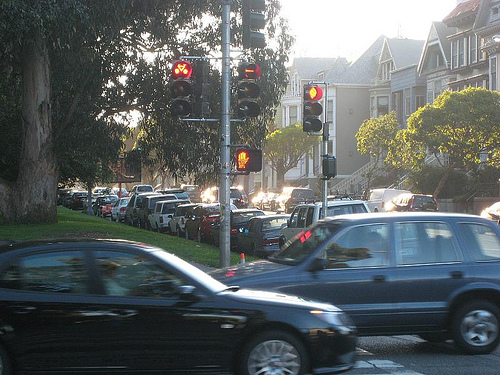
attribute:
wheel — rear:
[461, 306, 498, 350]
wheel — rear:
[251, 327, 293, 364]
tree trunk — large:
[14, 44, 68, 224]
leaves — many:
[92, 28, 159, 98]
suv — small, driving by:
[209, 210, 498, 352]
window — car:
[21, 246, 90, 301]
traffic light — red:
[302, 81, 323, 135]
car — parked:
[277, 200, 368, 255]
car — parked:
[238, 212, 293, 256]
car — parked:
[210, 207, 255, 244]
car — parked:
[146, 197, 191, 236]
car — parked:
[107, 197, 132, 221]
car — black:
[2, 236, 357, 373]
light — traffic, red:
[260, 65, 367, 132]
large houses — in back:
[276, 20, 471, 193]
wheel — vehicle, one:
[240, 321, 300, 373]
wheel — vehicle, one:
[450, 290, 499, 354]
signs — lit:
[178, 20, 265, 242]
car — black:
[2, 223, 360, 374]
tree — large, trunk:
[404, 76, 499, 196]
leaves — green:
[354, 84, 483, 178]